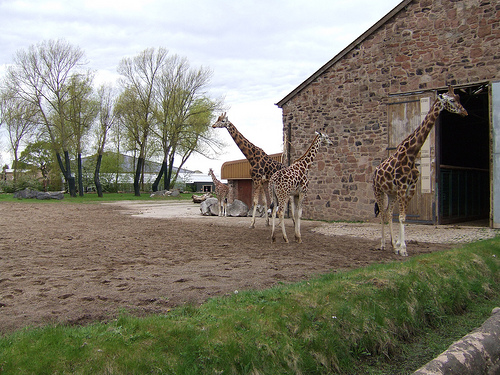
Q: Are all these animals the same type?
A: Yes, all the animals are giraffes.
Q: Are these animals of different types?
A: No, all the animals are giraffes.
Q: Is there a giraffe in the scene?
A: Yes, there are giraffes.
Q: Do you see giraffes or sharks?
A: Yes, there are giraffes.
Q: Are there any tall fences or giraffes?
A: Yes, there are tall giraffes.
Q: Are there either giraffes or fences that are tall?
A: Yes, the giraffes are tall.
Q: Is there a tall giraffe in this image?
A: Yes, there are tall giraffes.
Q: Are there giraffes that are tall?
A: Yes, there are giraffes that are tall.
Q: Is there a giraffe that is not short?
A: Yes, there are tall giraffes.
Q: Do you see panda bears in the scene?
A: No, there are no panda bears.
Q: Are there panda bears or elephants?
A: No, there are no panda bears or elephants.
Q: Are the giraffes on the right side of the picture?
A: Yes, the giraffes are on the right of the image.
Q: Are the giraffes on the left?
A: No, the giraffes are on the right of the image.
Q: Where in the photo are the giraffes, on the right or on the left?
A: The giraffes are on the right of the image.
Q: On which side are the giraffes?
A: The giraffes are on the right of the image.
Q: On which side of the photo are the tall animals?
A: The giraffes are on the right of the image.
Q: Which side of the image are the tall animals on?
A: The giraffes are on the right of the image.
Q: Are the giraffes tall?
A: Yes, the giraffes are tall.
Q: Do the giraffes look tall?
A: Yes, the giraffes are tall.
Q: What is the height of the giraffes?
A: The giraffes are tall.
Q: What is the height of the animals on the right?
A: The giraffes are tall.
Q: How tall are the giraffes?
A: The giraffes are tall.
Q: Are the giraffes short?
A: No, the giraffes are tall.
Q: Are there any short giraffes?
A: No, there are giraffes but they are tall.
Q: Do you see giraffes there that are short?
A: No, there are giraffes but they are tall.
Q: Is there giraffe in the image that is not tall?
A: No, there are giraffes but they are tall.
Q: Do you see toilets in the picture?
A: No, there are no toilets.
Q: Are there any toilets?
A: No, there are no toilets.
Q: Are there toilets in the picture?
A: No, there are no toilets.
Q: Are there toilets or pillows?
A: No, there are no toilets or pillows.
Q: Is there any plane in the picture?
A: No, there are no airplanes.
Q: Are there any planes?
A: No, there are no planes.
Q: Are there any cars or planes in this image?
A: No, there are no planes or cars.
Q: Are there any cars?
A: No, there are no cars.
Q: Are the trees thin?
A: Yes, the trees are thin.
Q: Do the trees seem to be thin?
A: Yes, the trees are thin.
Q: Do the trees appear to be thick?
A: No, the trees are thin.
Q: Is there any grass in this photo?
A: Yes, there is grass.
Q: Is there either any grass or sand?
A: Yes, there is grass.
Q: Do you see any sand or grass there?
A: Yes, there is grass.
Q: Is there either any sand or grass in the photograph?
A: Yes, there is grass.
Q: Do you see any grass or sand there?
A: Yes, there is grass.